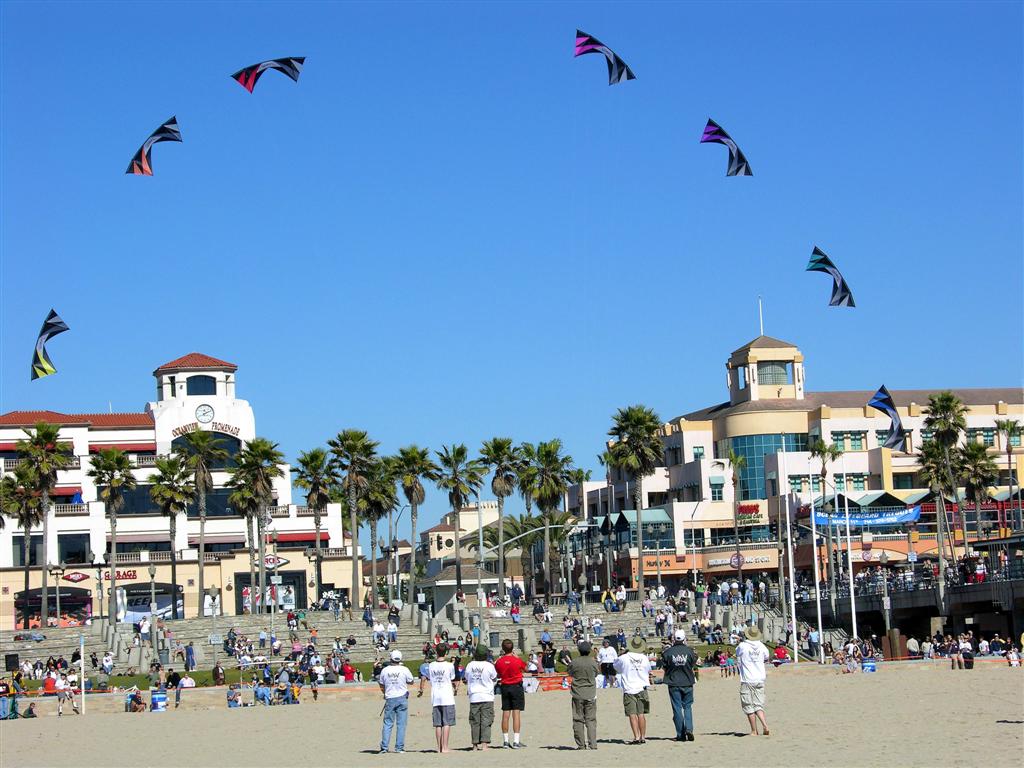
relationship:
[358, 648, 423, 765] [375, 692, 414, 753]
man wearing pants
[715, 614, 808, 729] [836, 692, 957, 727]
person standing on beach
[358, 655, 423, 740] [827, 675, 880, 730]
person standing on beach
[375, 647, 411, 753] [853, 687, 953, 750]
person standing on beach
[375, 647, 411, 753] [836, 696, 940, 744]
person standing on beach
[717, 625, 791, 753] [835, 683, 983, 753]
person standing on beach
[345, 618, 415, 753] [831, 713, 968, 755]
person standing on beach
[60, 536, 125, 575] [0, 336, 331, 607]
window on building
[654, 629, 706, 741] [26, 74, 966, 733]
person watching show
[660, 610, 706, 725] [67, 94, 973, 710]
spectator watching show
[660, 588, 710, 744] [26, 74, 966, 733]
spectator watching show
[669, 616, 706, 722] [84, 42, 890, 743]
spectator watching show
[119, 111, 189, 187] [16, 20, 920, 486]
kite in show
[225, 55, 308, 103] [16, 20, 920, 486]
kite in show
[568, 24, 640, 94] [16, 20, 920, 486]
kite in show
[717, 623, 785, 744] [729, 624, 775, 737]
person in person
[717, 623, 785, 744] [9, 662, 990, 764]
person on beach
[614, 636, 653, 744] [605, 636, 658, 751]
human worn by human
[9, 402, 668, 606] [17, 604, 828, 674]
trees on sidewalk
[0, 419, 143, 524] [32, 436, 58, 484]
leaves has leaves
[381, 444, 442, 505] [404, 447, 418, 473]
leaves has leaves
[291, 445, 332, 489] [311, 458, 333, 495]
leaves has leaves